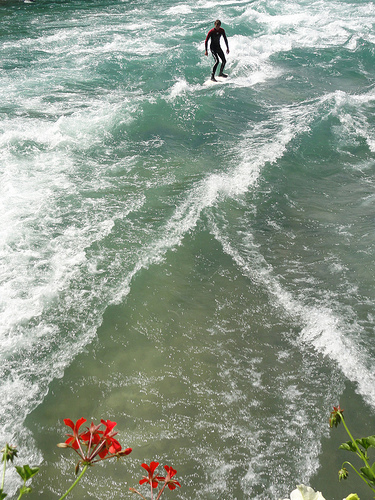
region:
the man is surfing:
[58, 19, 273, 279]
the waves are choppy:
[74, 249, 279, 377]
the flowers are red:
[74, 396, 155, 459]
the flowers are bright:
[67, 416, 153, 470]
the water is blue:
[63, 112, 183, 232]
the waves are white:
[55, 132, 169, 253]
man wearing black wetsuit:
[199, 18, 235, 83]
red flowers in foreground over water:
[58, 405, 190, 491]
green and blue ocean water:
[7, 1, 372, 485]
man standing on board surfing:
[197, 13, 243, 94]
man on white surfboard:
[200, 71, 236, 92]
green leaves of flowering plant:
[326, 398, 371, 496]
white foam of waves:
[8, 0, 372, 375]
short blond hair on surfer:
[212, 22, 220, 28]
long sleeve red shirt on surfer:
[202, 26, 232, 53]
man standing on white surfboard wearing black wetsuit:
[195, 18, 238, 89]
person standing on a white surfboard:
[202, 18, 234, 89]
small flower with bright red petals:
[136, 458, 162, 489]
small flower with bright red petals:
[61, 415, 89, 454]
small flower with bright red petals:
[106, 443, 133, 460]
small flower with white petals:
[286, 482, 327, 499]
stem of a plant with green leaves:
[2, 459, 42, 498]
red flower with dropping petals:
[327, 401, 346, 430]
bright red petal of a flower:
[73, 414, 88, 434]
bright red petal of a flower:
[61, 415, 78, 428]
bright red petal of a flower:
[62, 433, 76, 445]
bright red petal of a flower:
[102, 418, 117, 434]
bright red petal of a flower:
[147, 458, 158, 473]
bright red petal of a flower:
[140, 459, 152, 474]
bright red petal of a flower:
[160, 464, 175, 478]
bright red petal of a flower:
[137, 476, 147, 486]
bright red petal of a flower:
[168, 478, 185, 487]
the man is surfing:
[190, 4, 252, 94]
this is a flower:
[53, 408, 132, 474]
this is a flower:
[127, 450, 193, 498]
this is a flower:
[324, 401, 366, 491]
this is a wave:
[40, 103, 127, 171]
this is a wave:
[295, 308, 365, 406]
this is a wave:
[3, 354, 63, 430]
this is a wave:
[261, 107, 314, 157]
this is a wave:
[238, 10, 316, 97]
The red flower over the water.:
[58, 407, 129, 473]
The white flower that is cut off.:
[281, 476, 326, 498]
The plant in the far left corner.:
[2, 444, 37, 495]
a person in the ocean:
[203, 17, 239, 94]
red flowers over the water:
[52, 410, 180, 495]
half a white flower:
[280, 480, 320, 498]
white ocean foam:
[278, 285, 365, 388]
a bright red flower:
[80, 417, 99, 447]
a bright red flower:
[98, 417, 117, 447]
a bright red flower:
[117, 445, 133, 460]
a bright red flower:
[138, 460, 165, 495]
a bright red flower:
[156, 461, 180, 489]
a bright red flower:
[62, 436, 81, 452]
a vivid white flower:
[284, 480, 325, 498]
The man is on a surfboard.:
[202, 19, 228, 87]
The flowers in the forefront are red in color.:
[50, 417, 180, 498]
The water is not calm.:
[0, 1, 373, 419]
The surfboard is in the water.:
[202, 74, 234, 87]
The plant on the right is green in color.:
[325, 398, 372, 496]